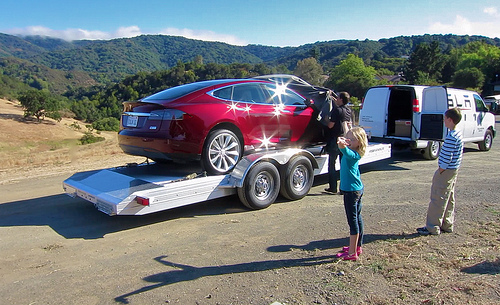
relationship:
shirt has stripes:
[438, 130, 465, 171] [442, 142, 464, 150]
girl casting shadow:
[334, 128, 369, 263] [114, 254, 355, 304]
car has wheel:
[118, 76, 348, 174] [203, 126, 243, 176]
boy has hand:
[417, 108, 464, 235] [437, 134, 456, 175]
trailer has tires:
[63, 143, 392, 220] [238, 153, 315, 210]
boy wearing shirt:
[417, 108, 464, 235] [438, 130, 465, 171]